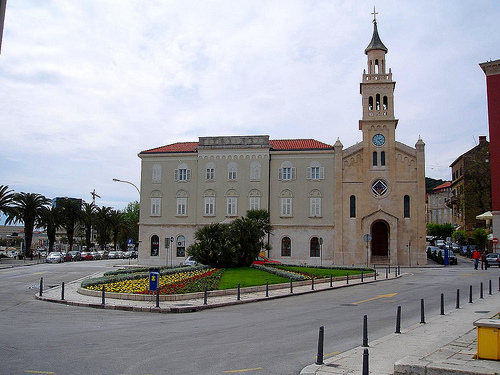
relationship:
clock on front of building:
[371, 132, 388, 149] [136, 6, 430, 269]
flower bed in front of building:
[83, 258, 372, 294] [136, 6, 430, 269]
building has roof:
[136, 6, 430, 269] [141, 136, 334, 155]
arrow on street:
[349, 290, 397, 303] [1, 257, 500, 374]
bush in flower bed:
[189, 208, 273, 266] [83, 258, 372, 294]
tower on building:
[358, 7, 399, 143] [136, 6, 430, 269]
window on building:
[280, 166, 293, 180] [136, 6, 430, 269]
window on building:
[310, 167, 321, 180] [136, 6, 430, 269]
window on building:
[251, 163, 262, 180] [136, 6, 430, 269]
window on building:
[227, 166, 238, 180] [136, 6, 430, 269]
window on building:
[204, 165, 217, 181] [136, 6, 430, 269]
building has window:
[136, 6, 430, 269] [204, 165, 217, 181]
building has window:
[136, 6, 430, 269] [227, 166, 238, 180]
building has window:
[136, 6, 430, 269] [251, 163, 262, 180]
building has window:
[136, 6, 430, 269] [280, 166, 293, 180]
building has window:
[136, 6, 430, 269] [310, 167, 321, 180]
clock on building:
[371, 132, 388, 149] [136, 6, 430, 269]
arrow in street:
[349, 290, 397, 303] [1, 257, 500, 374]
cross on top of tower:
[372, 6, 380, 20] [358, 7, 399, 143]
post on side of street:
[38, 275, 44, 299] [1, 257, 500, 374]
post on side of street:
[61, 281, 67, 303] [1, 257, 500, 374]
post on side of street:
[101, 284, 105, 303] [1, 257, 500, 374]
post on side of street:
[154, 287, 161, 307] [1, 257, 500, 374]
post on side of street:
[203, 286, 208, 308] [1, 257, 500, 374]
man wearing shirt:
[468, 248, 483, 270] [472, 251, 482, 260]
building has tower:
[136, 6, 430, 269] [358, 7, 399, 143]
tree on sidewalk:
[93, 202, 116, 250] [0, 258, 41, 270]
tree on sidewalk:
[81, 199, 101, 249] [0, 258, 41, 270]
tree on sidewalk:
[61, 198, 87, 251] [0, 258, 41, 270]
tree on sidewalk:
[37, 203, 66, 258] [0, 258, 41, 270]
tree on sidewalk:
[3, 193, 57, 257] [0, 258, 41, 270]